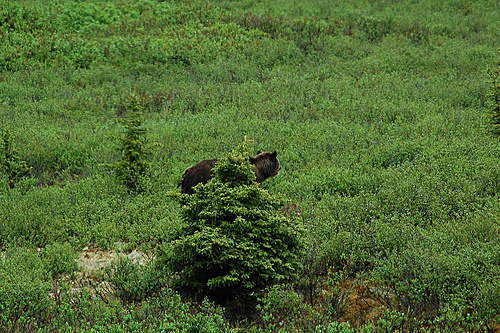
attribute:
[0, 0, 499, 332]
plants — green, small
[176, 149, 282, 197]
bear — big, black, large, looking at something, brown, wild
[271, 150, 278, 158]
ear — big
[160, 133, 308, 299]
tree — wide, short, evergreen, young, green, small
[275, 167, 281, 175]
mouth — open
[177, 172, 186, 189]
tail — short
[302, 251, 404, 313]
branches — bare, brown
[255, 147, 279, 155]
ears — rounded, small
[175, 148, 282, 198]
fur — rugged, brown, thick